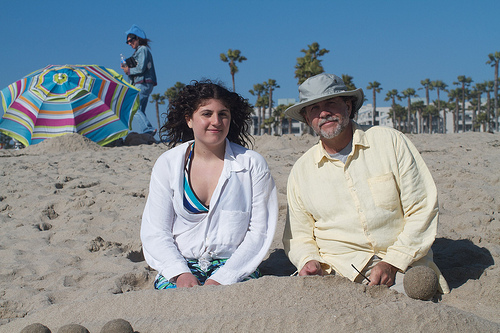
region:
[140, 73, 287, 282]
the woman in the sand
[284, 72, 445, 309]
the man in the sand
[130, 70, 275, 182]
the woman is smiling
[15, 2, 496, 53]
the sky is blue and clear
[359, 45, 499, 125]
the palm trees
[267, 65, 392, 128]
the man wearing the gray hat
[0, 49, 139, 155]
the umbrella on the sand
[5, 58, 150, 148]
the umbrella is open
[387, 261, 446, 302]
the ball of sand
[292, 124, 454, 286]
the man wearing the yellow shirt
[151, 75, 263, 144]
woman with brown hair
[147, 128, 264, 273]
woman wearing a white shirt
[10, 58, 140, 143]
rainbow umbrella on the beach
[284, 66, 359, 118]
man wearing a hat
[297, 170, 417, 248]
man wearing a yellow shirt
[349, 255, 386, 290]
man holding his glasses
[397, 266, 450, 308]
ball of sand on the beach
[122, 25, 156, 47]
woman wearing a blue hat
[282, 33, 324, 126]
tree near the beach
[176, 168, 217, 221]
woman wearing a pink bikini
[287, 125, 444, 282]
Man wearing a shirt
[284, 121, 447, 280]
Man is wearing a shirt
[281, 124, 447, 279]
Man wearing a yellow shirt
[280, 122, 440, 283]
Man is wearing a yellow shirt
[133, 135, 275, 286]
Woman wearing a shirt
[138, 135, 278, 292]
Woman is wearing a shirt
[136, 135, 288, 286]
Woman wearing a white shirt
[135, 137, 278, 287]
Woman is wearing a white shirt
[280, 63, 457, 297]
Man is on the sand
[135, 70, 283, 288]
Woman is on the sand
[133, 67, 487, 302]
man and lady sitting on the beach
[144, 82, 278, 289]
lady wearing white shirt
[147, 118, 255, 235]
lady wearing blue and white striped top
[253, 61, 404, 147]
man wearing grey hat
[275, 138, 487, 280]
man wearing yellow shirt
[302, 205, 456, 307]
man wearing brown pants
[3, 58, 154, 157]
striped umbrella on the beach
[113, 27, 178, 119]
lady walking on the beach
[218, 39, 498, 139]
palm trees in the background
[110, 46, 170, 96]
lady holding water bottle